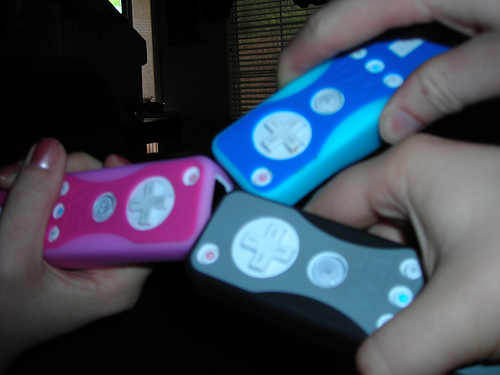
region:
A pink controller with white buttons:
[33, 150, 239, 268]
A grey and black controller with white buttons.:
[177, 184, 499, 374]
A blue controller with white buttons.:
[208, 12, 478, 209]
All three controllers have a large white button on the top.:
[115, 106, 313, 277]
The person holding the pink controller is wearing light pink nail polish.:
[2, 136, 142, 230]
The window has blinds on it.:
[222, 2, 325, 132]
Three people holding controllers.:
[1, 1, 498, 371]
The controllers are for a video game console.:
[21, 23, 456, 345]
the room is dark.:
[1, 3, 488, 373]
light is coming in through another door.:
[111, 3, 156, 163]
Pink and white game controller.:
[42, 158, 225, 263]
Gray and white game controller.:
[189, 192, 426, 332]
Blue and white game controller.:
[208, 36, 445, 205]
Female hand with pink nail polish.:
[2, 131, 152, 354]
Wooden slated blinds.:
[225, 1, 324, 114]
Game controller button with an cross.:
[122, 175, 174, 233]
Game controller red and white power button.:
[250, 167, 270, 186]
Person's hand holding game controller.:
[274, 1, 497, 145]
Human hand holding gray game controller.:
[302, 131, 499, 373]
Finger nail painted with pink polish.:
[28, 136, 62, 175]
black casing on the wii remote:
[204, 189, 491, 370]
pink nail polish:
[6, 135, 70, 175]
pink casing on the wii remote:
[22, 155, 224, 248]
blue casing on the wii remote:
[204, 18, 471, 200]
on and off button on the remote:
[176, 167, 212, 191]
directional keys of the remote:
[235, 218, 297, 277]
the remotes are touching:
[145, 119, 380, 321]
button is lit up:
[384, 286, 427, 307]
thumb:
[381, 74, 488, 136]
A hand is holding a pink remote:
[3, 139, 237, 366]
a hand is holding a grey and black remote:
[194, 133, 499, 371]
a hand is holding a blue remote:
[214, 0, 490, 205]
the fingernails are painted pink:
[19, 136, 66, 176]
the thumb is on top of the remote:
[0, 137, 68, 271]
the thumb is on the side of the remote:
[369, 29, 499, 144]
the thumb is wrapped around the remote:
[349, 271, 471, 373]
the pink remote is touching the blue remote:
[33, 158, 228, 275]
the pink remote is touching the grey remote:
[39, 155, 424, 357]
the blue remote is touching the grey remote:
[189, 26, 468, 372]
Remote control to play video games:
[185, 175, 489, 373]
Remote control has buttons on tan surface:
[185, 175, 450, 355]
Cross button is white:
[220, 210, 300, 280]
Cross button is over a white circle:
[220, 210, 300, 285]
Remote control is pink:
[25, 135, 235, 270]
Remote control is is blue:
[210, 21, 455, 201]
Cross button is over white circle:
[116, 170, 176, 230]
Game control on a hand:
[13, 131, 221, 316]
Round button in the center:
[84, 186, 119, 228]